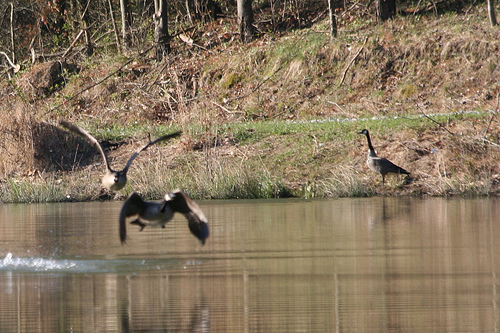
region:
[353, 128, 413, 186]
goose on bank of pond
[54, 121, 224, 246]
geese flying over the water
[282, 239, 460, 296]
water is calm and reflective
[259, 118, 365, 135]
green grass on side of pond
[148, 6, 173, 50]
tree trunk near pond of water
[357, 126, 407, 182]
goose is black and gray in color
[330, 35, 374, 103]
dead tree limbs on hill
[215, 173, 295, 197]
tall grass on bank of pond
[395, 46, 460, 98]
grass is brown on side of hill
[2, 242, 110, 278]
water is being splashed by birds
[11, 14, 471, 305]
ducks on the lake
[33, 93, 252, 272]
these ducks are flying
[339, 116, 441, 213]
this duck is standing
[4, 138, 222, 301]
these ducks are making waves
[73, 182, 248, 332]
the duck's reflection on the water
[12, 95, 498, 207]
grass in the background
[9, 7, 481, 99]
trees near the lake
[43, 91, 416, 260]
three ducks in the picture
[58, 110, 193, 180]
this duck has extended wings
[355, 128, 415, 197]
this duck is being observant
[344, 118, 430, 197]
This is a bird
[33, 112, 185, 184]
This is a bird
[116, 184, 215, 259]
This is a bird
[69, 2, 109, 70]
Trunk of a tree partly seen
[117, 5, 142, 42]
Trunk of a tree partly seen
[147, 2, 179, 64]
Trunk of a tree partly seen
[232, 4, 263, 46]
Trunk of a tree partly seen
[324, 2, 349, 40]
Trunk of a tree partly seen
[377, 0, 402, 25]
Trunk of a tree partly seen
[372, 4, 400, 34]
Trunk of a tree partly seen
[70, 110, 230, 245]
two birds flying over water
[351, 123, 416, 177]
bird standing beside water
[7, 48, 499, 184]
embankment besides the river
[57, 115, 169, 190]
bird flapping it's wings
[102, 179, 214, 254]
bird in front with wings flapping down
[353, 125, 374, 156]
black face and neck of bird on embankment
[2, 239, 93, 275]
splash mark in river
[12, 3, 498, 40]
tree trunks along embankment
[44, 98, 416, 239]
three birds around the river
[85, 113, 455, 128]
grass strip on embankment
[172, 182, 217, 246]
Wings of a bird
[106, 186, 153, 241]
Wings of a bird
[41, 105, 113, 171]
Wings of a bird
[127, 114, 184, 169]
Wings of a bird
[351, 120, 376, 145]
Head of a bird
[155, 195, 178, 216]
Head of a bird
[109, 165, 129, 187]
Head of a bird